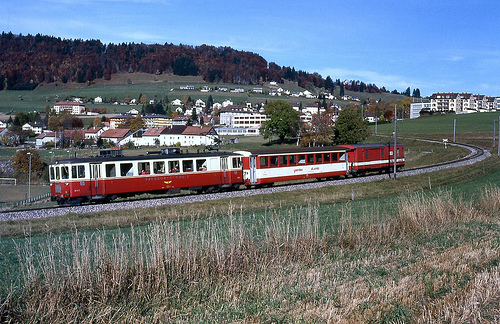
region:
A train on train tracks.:
[40, 143, 446, 184]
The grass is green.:
[63, 216, 348, 234]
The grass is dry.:
[328, 248, 495, 321]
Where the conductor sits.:
[37, 152, 93, 210]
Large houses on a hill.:
[401, 87, 498, 134]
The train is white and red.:
[103, 143, 293, 209]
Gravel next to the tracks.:
[13, 207, 128, 225]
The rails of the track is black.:
[433, 135, 490, 185]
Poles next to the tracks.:
[443, 113, 499, 163]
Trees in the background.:
[20, 35, 267, 89]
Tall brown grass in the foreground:
[11, 231, 492, 318]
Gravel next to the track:
[2, 205, 121, 214]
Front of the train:
[45, 161, 73, 203]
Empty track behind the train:
[408, 128, 486, 171]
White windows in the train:
[103, 158, 216, 177]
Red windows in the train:
[253, 151, 348, 166]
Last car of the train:
[350, 141, 405, 174]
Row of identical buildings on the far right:
[425, 86, 499, 116]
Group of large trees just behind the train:
[261, 100, 373, 146]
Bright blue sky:
[242, 9, 493, 49]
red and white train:
[47, 159, 256, 204]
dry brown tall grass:
[17, 232, 427, 290]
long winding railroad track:
[387, 129, 499, 177]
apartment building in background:
[411, 79, 491, 122]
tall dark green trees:
[3, 24, 282, 85]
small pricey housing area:
[45, 89, 252, 141]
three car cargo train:
[43, 140, 452, 207]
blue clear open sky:
[16, 3, 498, 49]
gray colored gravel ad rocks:
[39, 194, 294, 218]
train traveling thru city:
[21, 22, 488, 257]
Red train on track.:
[47, 142, 409, 197]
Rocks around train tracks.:
[6, 132, 491, 220]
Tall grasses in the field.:
[16, 200, 498, 319]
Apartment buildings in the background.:
[407, 89, 498, 122]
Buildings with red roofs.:
[32, 97, 255, 144]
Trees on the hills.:
[0, 32, 422, 101]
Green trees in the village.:
[257, 104, 378, 146]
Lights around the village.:
[17, 91, 471, 203]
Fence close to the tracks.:
[15, 189, 50, 211]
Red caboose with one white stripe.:
[340, 143, 405, 177]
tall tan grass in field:
[49, 224, 121, 266]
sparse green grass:
[191, 279, 306, 322]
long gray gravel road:
[103, 197, 265, 209]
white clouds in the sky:
[324, 58, 397, 75]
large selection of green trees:
[104, 32, 297, 90]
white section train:
[248, 162, 358, 179]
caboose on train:
[349, 132, 436, 169]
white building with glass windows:
[208, 104, 279, 130]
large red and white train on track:
[43, 140, 365, 190]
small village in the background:
[52, 71, 349, 144]